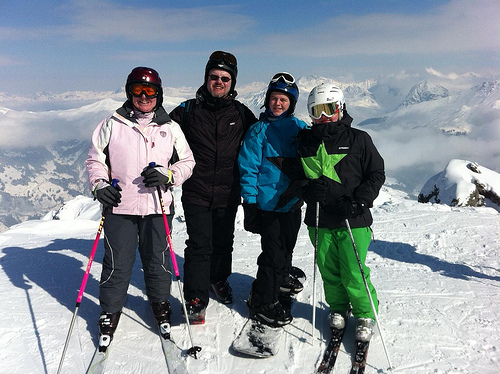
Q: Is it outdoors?
A: Yes, it is outdoors.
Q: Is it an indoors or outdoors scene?
A: It is outdoors.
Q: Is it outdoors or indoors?
A: It is outdoors.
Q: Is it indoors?
A: No, it is outdoors.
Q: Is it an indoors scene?
A: No, it is outdoors.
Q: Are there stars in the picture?
A: Yes, there is a star.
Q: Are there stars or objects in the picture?
A: Yes, there is a star.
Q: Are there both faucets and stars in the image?
A: No, there is a star but no faucets.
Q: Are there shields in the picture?
A: No, there are no shields.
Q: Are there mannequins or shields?
A: No, there are no shields or mannequins.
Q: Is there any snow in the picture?
A: Yes, there is snow.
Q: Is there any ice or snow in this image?
A: Yes, there is snow.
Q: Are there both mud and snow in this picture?
A: No, there is snow but no mud.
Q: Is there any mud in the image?
A: No, there is no mud.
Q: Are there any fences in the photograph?
A: No, there are no fences.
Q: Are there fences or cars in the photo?
A: No, there are no fences or cars.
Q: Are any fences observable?
A: No, there are no fences.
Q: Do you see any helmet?
A: Yes, there is a helmet.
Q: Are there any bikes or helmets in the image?
A: Yes, there is a helmet.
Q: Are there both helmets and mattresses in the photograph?
A: No, there is a helmet but no mattresses.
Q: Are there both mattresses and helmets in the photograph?
A: No, there is a helmet but no mattresses.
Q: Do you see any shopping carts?
A: No, there are no shopping carts.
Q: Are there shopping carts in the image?
A: No, there are no shopping carts.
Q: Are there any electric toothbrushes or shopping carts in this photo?
A: No, there are no shopping carts or electric toothbrushes.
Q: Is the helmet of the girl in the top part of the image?
A: Yes, the helmet is in the top of the image.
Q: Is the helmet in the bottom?
A: No, the helmet is in the top of the image.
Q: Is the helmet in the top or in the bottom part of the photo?
A: The helmet is in the top of the image.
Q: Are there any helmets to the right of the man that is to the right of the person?
A: Yes, there is a helmet to the right of the man.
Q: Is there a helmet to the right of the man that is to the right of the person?
A: Yes, there is a helmet to the right of the man.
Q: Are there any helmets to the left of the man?
A: No, the helmet is to the right of the man.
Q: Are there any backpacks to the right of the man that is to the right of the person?
A: No, there is a helmet to the right of the man.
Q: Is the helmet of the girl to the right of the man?
A: Yes, the helmet is to the right of the man.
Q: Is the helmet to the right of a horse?
A: No, the helmet is to the right of the man.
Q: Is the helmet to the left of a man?
A: No, the helmet is to the right of a man.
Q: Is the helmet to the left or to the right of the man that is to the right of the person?
A: The helmet is to the right of the man.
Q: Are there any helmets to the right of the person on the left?
A: Yes, there is a helmet to the right of the person.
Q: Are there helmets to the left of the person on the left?
A: No, the helmet is to the right of the person.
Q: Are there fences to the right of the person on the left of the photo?
A: No, there is a helmet to the right of the person.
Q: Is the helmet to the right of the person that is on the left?
A: Yes, the helmet is to the right of the person.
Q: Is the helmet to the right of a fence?
A: No, the helmet is to the right of the person.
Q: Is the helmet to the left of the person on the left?
A: No, the helmet is to the right of the person.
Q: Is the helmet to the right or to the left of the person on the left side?
A: The helmet is to the right of the person.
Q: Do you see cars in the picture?
A: No, there are no cars.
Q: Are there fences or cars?
A: No, there are no cars or fences.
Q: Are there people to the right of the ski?
A: No, the person is to the left of the ski.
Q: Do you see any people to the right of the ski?
A: No, the person is to the left of the ski.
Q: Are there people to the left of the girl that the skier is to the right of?
A: Yes, there is a person to the left of the girl.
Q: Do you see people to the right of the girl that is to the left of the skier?
A: No, the person is to the left of the girl.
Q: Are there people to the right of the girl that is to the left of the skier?
A: No, the person is to the left of the girl.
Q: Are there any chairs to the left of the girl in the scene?
A: No, there is a person to the left of the girl.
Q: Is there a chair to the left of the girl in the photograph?
A: No, there is a person to the left of the girl.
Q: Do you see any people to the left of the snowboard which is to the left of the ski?
A: Yes, there is a person to the left of the snowboard.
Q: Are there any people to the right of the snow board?
A: No, the person is to the left of the snow board.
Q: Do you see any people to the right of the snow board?
A: No, the person is to the left of the snow board.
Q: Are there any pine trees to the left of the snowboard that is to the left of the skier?
A: No, there is a person to the left of the snowboard.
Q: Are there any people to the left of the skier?
A: Yes, there is a person to the left of the skier.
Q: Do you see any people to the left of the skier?
A: Yes, there is a person to the left of the skier.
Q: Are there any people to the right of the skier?
A: No, the person is to the left of the skier.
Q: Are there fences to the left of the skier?
A: No, there is a person to the left of the skier.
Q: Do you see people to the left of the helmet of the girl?
A: Yes, there is a person to the left of the helmet.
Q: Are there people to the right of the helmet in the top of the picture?
A: No, the person is to the left of the helmet.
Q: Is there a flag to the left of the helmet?
A: No, there is a person to the left of the helmet.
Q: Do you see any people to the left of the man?
A: Yes, there is a person to the left of the man.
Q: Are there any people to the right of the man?
A: No, the person is to the left of the man.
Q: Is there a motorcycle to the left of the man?
A: No, there is a person to the left of the man.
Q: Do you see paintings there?
A: No, there are no paintings.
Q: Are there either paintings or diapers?
A: No, there are no paintings or diapers.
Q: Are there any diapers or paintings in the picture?
A: No, there are no paintings or diapers.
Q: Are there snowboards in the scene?
A: Yes, there is a snowboard.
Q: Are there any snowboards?
A: Yes, there is a snowboard.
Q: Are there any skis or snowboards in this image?
A: Yes, there is a snowboard.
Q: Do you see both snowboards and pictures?
A: No, there is a snowboard but no pictures.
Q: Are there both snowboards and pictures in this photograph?
A: No, there is a snowboard but no pictures.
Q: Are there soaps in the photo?
A: No, there are no soaps.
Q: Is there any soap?
A: No, there are no soaps.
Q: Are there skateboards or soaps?
A: No, there are no soaps or skateboards.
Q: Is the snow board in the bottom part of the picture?
A: Yes, the snow board is in the bottom of the image.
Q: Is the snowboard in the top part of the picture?
A: No, the snowboard is in the bottom of the image.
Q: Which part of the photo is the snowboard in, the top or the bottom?
A: The snowboard is in the bottom of the image.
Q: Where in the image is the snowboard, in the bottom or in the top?
A: The snowboard is in the bottom of the image.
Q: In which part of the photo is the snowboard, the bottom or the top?
A: The snowboard is in the bottom of the image.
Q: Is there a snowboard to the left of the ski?
A: Yes, there is a snowboard to the left of the ski.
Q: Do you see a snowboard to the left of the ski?
A: Yes, there is a snowboard to the left of the ski.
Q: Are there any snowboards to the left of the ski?
A: Yes, there is a snowboard to the left of the ski.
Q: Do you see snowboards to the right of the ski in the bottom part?
A: No, the snowboard is to the left of the ski.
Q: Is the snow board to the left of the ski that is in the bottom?
A: Yes, the snow board is to the left of the ski.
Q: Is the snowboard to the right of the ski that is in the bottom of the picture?
A: No, the snowboard is to the left of the ski.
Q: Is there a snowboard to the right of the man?
A: Yes, there is a snowboard to the right of the man.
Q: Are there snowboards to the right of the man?
A: Yes, there is a snowboard to the right of the man.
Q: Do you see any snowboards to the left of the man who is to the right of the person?
A: No, the snowboard is to the right of the man.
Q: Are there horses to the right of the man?
A: No, there is a snowboard to the right of the man.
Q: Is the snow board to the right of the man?
A: Yes, the snow board is to the right of the man.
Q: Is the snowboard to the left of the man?
A: No, the snowboard is to the right of the man.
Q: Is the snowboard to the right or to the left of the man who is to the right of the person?
A: The snowboard is to the right of the man.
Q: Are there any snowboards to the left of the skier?
A: Yes, there is a snowboard to the left of the skier.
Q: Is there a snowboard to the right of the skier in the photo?
A: No, the snowboard is to the left of the skier.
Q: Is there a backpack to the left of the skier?
A: No, there is a snowboard to the left of the skier.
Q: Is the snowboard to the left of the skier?
A: Yes, the snowboard is to the left of the skier.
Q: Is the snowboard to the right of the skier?
A: No, the snowboard is to the left of the skier.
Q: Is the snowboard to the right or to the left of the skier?
A: The snowboard is to the left of the skier.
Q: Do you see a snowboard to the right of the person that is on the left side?
A: Yes, there is a snowboard to the right of the person.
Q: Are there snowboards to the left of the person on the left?
A: No, the snowboard is to the right of the person.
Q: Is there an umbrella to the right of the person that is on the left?
A: No, there is a snowboard to the right of the person.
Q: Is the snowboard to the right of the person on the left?
A: Yes, the snowboard is to the right of the person.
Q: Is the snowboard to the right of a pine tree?
A: No, the snowboard is to the right of the person.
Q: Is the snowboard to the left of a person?
A: No, the snowboard is to the right of a person.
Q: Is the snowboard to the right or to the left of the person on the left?
A: The snowboard is to the right of the person.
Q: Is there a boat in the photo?
A: No, there are no boats.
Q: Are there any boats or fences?
A: No, there are no boats or fences.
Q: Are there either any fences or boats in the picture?
A: No, there are no boats or fences.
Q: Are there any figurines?
A: No, there are no figurines.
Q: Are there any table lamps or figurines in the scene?
A: No, there are no figurines or table lamps.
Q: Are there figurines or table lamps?
A: No, there are no figurines or table lamps.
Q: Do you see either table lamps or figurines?
A: No, there are no figurines or table lamps.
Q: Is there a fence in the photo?
A: No, there are no fences.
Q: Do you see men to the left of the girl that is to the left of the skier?
A: Yes, there is a man to the left of the girl.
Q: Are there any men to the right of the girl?
A: No, the man is to the left of the girl.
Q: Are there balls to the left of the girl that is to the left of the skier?
A: No, there is a man to the left of the girl.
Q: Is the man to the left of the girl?
A: Yes, the man is to the left of the girl.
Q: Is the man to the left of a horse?
A: No, the man is to the left of the girl.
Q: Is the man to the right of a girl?
A: No, the man is to the left of a girl.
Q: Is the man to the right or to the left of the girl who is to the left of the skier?
A: The man is to the left of the girl.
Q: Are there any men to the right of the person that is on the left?
A: Yes, there is a man to the right of the person.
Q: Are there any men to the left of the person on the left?
A: No, the man is to the right of the person.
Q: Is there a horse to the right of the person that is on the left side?
A: No, there is a man to the right of the person.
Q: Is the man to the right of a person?
A: Yes, the man is to the right of a person.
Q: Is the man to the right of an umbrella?
A: No, the man is to the right of a person.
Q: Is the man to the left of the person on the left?
A: No, the man is to the right of the person.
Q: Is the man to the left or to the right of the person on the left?
A: The man is to the right of the person.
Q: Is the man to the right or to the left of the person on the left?
A: The man is to the right of the person.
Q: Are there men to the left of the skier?
A: Yes, there is a man to the left of the skier.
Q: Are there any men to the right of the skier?
A: No, the man is to the left of the skier.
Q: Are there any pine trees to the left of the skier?
A: No, there is a man to the left of the skier.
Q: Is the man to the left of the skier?
A: Yes, the man is to the left of the skier.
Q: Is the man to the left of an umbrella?
A: No, the man is to the left of the skier.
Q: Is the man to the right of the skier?
A: No, the man is to the left of the skier.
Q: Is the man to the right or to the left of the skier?
A: The man is to the left of the skier.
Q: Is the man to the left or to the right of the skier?
A: The man is to the left of the skier.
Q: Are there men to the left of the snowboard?
A: Yes, there is a man to the left of the snowboard.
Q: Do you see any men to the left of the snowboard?
A: Yes, there is a man to the left of the snowboard.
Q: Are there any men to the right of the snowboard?
A: No, the man is to the left of the snowboard.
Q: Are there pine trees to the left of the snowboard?
A: No, there is a man to the left of the snowboard.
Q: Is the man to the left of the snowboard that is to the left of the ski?
A: Yes, the man is to the left of the snowboard.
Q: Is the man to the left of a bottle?
A: No, the man is to the left of the snowboard.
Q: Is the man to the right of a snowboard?
A: No, the man is to the left of a snowboard.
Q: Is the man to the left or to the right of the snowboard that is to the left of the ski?
A: The man is to the left of the snowboard.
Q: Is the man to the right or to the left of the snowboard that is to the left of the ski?
A: The man is to the left of the snowboard.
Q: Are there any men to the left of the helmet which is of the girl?
A: Yes, there is a man to the left of the helmet.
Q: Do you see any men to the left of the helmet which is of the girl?
A: Yes, there is a man to the left of the helmet.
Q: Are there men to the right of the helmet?
A: No, the man is to the left of the helmet.